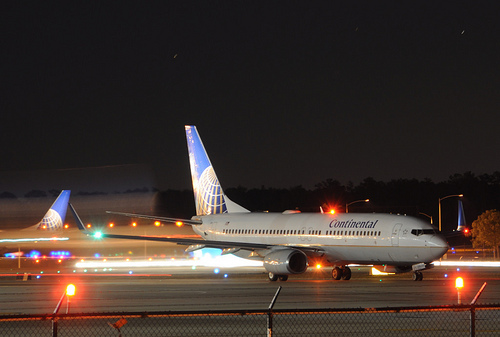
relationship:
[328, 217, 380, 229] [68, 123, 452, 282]
continental written on plane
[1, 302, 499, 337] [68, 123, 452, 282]
fence in front of plane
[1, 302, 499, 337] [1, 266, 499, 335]
fence in front of runway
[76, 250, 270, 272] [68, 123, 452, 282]
glare behind plane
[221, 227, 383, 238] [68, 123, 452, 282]
windows on plane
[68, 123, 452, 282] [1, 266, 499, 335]
plane on runway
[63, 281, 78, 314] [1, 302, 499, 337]
light on fence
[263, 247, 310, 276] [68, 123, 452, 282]
engine on plane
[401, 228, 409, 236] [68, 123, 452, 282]
star on plane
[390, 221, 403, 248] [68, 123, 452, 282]
door on plane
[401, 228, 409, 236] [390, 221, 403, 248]
star next to door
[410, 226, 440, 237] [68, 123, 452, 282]
windshield on plane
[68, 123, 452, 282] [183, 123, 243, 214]
plane has tail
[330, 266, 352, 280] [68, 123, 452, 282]
wheels on plane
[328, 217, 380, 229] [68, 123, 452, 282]
continental logo on plane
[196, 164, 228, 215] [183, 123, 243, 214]
globe printed on tail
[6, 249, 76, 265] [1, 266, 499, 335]
lights on runway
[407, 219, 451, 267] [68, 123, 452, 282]
nose of plane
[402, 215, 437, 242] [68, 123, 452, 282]
cockpit on plane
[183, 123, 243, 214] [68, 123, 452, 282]
tail on plane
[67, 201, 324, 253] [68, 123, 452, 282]
wing on plane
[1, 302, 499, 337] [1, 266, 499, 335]
fence beside runway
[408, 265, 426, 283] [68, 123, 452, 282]
landing gear on plane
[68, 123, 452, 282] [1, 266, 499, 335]
plane parked on runway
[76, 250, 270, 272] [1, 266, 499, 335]
glare on runway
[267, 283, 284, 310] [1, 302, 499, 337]
pole on fence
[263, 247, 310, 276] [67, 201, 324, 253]
engine under wing